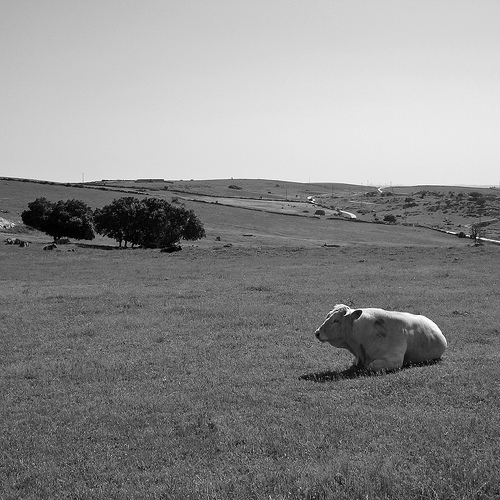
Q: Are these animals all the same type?
A: Yes, all the animals are cows.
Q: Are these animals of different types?
A: No, all the animals are cows.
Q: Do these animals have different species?
A: No, all the animals are cows.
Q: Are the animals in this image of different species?
A: No, all the animals are cows.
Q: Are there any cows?
A: Yes, there is a cow.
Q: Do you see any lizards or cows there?
A: Yes, there is a cow.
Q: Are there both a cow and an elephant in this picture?
A: No, there is a cow but no elephants.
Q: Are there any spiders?
A: No, there are no spiders.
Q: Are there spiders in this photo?
A: No, there are no spiders.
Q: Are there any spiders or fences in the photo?
A: No, there are no spiders or fences.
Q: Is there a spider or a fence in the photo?
A: No, there are no spiders or fences.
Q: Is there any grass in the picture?
A: Yes, there is grass.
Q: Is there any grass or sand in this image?
A: Yes, there is grass.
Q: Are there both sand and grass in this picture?
A: No, there is grass but no sand.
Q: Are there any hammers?
A: No, there are no hammers.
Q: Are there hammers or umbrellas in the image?
A: No, there are no hammers or umbrellas.